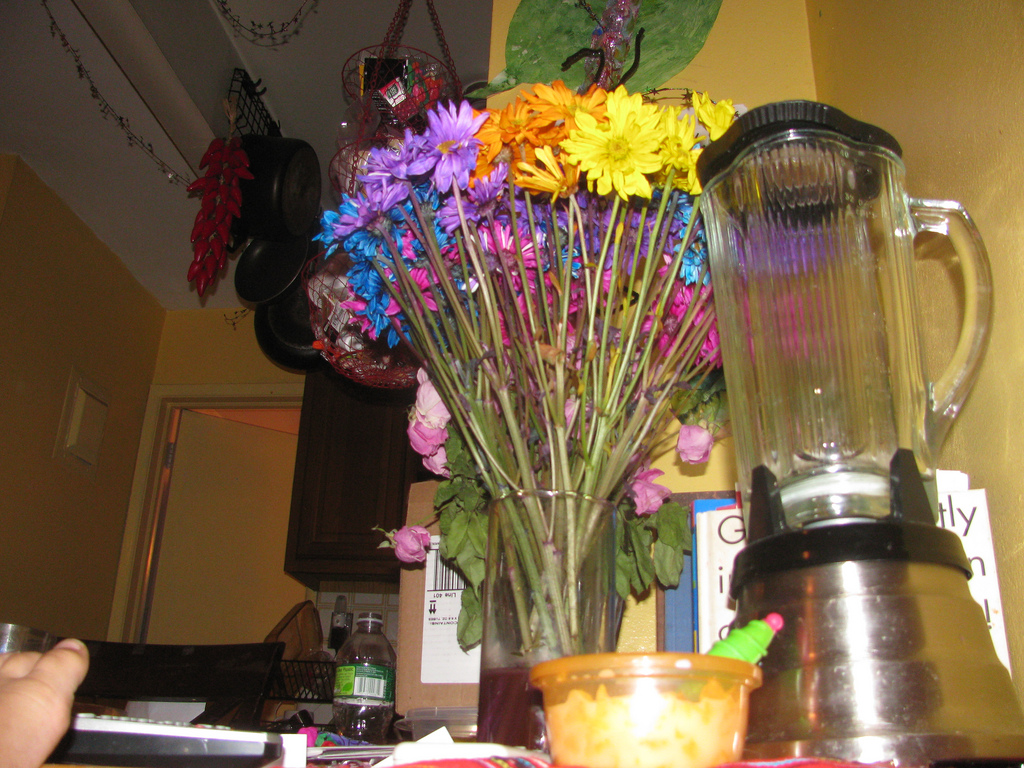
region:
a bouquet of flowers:
[280, 25, 783, 765]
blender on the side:
[647, 45, 992, 764]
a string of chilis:
[170, 95, 272, 307]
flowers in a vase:
[314, 29, 827, 764]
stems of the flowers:
[384, 203, 721, 602]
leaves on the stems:
[409, 423, 722, 661]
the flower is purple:
[385, 80, 503, 216]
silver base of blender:
[691, 510, 993, 764]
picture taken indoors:
[22, 25, 1009, 766]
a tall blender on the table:
[682, 107, 1019, 712]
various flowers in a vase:
[316, 41, 769, 766]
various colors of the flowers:
[269, 56, 741, 357]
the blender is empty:
[704, 125, 965, 538]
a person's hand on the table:
[15, 631, 92, 765]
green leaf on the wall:
[484, 10, 754, 99]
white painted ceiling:
[54, 32, 166, 238]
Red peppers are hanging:
[181, 131, 251, 300]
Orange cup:
[525, 650, 757, 761]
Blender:
[691, 95, 1015, 760]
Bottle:
[333, 610, 395, 741]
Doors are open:
[134, 407, 324, 643]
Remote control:
[51, 710, 277, 767]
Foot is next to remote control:
[0, 633, 90, 766]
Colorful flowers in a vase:
[317, 81, 738, 739]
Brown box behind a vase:
[393, 480, 482, 724]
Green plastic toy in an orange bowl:
[677, 610, 786, 702]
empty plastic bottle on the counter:
[329, 619, 397, 746]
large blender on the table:
[694, 98, 1008, 766]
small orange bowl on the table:
[531, 611, 791, 761]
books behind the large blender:
[683, 470, 1013, 667]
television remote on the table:
[61, 705, 274, 763]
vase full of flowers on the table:
[324, 95, 755, 751]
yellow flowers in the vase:
[582, 92, 738, 194]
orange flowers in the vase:
[465, 85, 609, 188]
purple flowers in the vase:
[354, 116, 677, 276]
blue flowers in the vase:
[310, 189, 447, 335]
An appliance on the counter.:
[695, 96, 1022, 765]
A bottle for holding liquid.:
[331, 607, 398, 744]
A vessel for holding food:
[531, 649, 760, 766]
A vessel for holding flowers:
[474, 490, 618, 746]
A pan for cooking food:
[234, 226, 314, 312]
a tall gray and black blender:
[681, 91, 1018, 766]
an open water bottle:
[333, 606, 400, 743]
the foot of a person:
[4, 628, 94, 765]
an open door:
[138, 398, 320, 655]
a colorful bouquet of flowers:
[305, 79, 701, 645]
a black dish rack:
[263, 651, 343, 699]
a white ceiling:
[49, 183, 258, 319]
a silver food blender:
[682, 94, 1022, 765]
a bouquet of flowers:
[299, 73, 783, 756]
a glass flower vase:
[473, 483, 632, 758]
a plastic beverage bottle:
[326, 612, 406, 759]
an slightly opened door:
[111, 376, 323, 661]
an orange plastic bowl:
[520, 653, 761, 767]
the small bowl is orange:
[525, 653, 757, 767]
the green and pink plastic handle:
[668, 610, 783, 700]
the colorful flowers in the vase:
[305, 81, 831, 749]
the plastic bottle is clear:
[332, 609, 399, 743]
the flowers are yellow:
[567, 82, 754, 513]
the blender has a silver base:
[691, 98, 1020, 766]